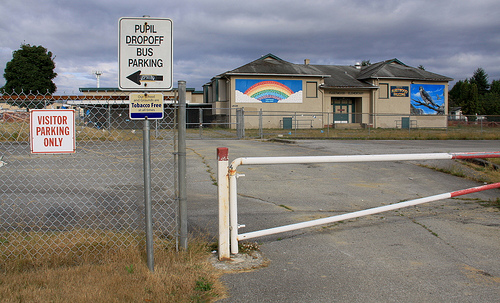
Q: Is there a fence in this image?
A: Yes, there is a fence.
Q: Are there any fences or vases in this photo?
A: Yes, there is a fence.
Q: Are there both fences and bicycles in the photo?
A: No, there is a fence but no bicycles.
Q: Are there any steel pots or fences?
A: Yes, there is a steel fence.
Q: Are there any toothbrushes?
A: No, there are no toothbrushes.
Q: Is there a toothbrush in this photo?
A: No, there are no toothbrushes.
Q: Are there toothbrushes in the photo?
A: No, there are no toothbrushes.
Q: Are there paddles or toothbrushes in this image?
A: No, there are no toothbrushes or paddles.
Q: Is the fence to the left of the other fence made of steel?
A: Yes, the fence is made of steel.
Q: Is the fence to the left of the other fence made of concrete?
A: No, the fence is made of steel.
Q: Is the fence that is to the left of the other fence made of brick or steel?
A: The fence is made of steel.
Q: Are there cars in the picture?
A: No, there are no cars.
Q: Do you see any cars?
A: No, there are no cars.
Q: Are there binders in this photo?
A: No, there are no binders.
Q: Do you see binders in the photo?
A: No, there are no binders.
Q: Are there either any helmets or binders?
A: No, there are no binders or helmets.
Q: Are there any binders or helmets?
A: No, there are no binders or helmets.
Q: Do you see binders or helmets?
A: No, there are no binders or helmets.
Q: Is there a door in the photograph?
A: Yes, there is a door.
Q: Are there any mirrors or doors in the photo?
A: Yes, there is a door.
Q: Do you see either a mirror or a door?
A: Yes, there is a door.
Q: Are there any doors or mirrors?
A: Yes, there is a door.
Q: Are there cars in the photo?
A: No, there are no cars.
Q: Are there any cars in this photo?
A: No, there are no cars.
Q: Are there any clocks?
A: No, there are no clocks.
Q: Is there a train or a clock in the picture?
A: No, there are no clocks or trains.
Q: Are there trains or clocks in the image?
A: No, there are no clocks or trains.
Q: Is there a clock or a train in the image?
A: No, there are no clocks or trains.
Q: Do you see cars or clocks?
A: No, there are no cars or clocks.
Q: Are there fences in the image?
A: Yes, there is a fence.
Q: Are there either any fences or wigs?
A: Yes, there is a fence.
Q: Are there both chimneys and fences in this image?
A: No, there is a fence but no chimneys.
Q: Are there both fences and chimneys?
A: No, there is a fence but no chimneys.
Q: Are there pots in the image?
A: No, there are no pots.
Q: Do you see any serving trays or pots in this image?
A: No, there are no pots or serving trays.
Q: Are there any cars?
A: No, there are no cars.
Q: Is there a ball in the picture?
A: No, there are no balls.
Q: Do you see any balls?
A: No, there are no balls.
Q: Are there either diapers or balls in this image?
A: No, there are no balls or diapers.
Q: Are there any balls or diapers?
A: No, there are no balls or diapers.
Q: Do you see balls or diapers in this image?
A: No, there are no balls or diapers.